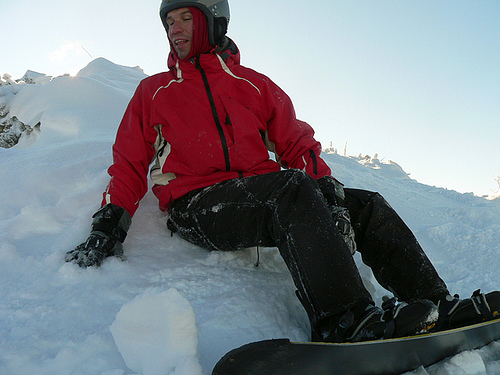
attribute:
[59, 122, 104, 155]
snow — white, clumpy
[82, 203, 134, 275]
glove — black, long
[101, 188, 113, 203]
label — small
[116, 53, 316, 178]
jacket — red, white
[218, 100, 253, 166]
mark — black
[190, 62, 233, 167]
zipper — black, long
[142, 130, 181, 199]
cut — small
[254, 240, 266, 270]
string — black, small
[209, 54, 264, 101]
line — white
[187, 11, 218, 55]
scarf — red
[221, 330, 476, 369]
snowboard — black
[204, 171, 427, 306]
pants — black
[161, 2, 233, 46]
helmet — black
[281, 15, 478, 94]
sky — blue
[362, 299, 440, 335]
boot — black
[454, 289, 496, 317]
boot — black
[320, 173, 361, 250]
glove — black